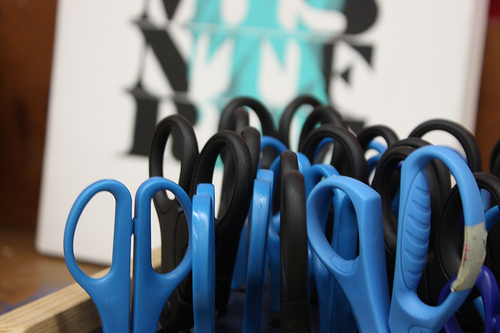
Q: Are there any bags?
A: No, there are no bags.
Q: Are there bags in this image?
A: No, there are no bags.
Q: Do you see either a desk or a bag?
A: No, there are no bags or desks.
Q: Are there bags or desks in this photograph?
A: No, there are no bags or desks.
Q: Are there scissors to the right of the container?
A: Yes, there are scissors to the right of the container.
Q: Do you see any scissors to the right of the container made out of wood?
A: Yes, there are scissors to the right of the container.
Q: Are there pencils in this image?
A: No, there are no pencils.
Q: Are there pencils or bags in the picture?
A: No, there are no pencils or bags.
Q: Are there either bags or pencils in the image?
A: No, there are no pencils or bags.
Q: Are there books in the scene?
A: No, there are no books.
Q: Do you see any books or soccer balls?
A: No, there are no books or soccer balls.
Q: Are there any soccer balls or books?
A: No, there are no books or soccer balls.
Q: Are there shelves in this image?
A: No, there are no shelves.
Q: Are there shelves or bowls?
A: No, there are no shelves or bowls.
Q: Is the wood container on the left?
A: Yes, the container is on the left of the image.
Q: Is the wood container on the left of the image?
A: Yes, the container is on the left of the image.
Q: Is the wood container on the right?
A: No, the container is on the left of the image.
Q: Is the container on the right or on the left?
A: The container is on the left of the image.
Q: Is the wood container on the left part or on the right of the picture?
A: The container is on the left of the image.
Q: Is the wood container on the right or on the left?
A: The container is on the left of the image.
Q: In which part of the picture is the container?
A: The container is on the left of the image.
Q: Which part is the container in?
A: The container is on the left of the image.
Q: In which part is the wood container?
A: The container is on the left of the image.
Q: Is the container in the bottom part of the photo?
A: Yes, the container is in the bottom of the image.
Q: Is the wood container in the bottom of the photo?
A: Yes, the container is in the bottom of the image.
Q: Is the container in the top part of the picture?
A: No, the container is in the bottom of the image.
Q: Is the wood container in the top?
A: No, the container is in the bottom of the image.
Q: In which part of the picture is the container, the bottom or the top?
A: The container is in the bottom of the image.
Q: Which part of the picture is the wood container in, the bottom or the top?
A: The container is in the bottom of the image.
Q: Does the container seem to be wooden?
A: Yes, the container is wooden.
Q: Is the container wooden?
A: Yes, the container is wooden.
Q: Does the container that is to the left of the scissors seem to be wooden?
A: Yes, the container is wooden.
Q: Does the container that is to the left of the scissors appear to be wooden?
A: Yes, the container is wooden.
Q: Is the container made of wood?
A: Yes, the container is made of wood.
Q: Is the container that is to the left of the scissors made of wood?
A: Yes, the container is made of wood.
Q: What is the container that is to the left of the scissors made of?
A: The container is made of wood.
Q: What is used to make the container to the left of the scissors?
A: The container is made of wood.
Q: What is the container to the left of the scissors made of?
A: The container is made of wood.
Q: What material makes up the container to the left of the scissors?
A: The container is made of wood.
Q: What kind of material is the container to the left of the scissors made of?
A: The container is made of wood.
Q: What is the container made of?
A: The container is made of wood.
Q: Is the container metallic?
A: No, the container is wooden.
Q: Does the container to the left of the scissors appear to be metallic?
A: No, the container is wooden.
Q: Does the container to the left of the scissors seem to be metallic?
A: No, the container is wooden.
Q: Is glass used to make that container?
A: No, the container is made of wood.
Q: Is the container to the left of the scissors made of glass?
A: No, the container is made of wood.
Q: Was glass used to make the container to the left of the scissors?
A: No, the container is made of wood.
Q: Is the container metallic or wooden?
A: The container is wooden.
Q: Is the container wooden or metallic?
A: The container is wooden.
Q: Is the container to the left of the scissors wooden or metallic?
A: The container is wooden.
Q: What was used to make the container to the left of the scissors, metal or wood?
A: The container is made of wood.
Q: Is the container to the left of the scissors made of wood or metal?
A: The container is made of wood.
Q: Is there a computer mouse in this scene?
A: No, there are no computer mice.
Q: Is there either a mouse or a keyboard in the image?
A: No, there are no computer mice or keyboards.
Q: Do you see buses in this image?
A: No, there are no buses.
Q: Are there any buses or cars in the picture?
A: No, there are no buses or cars.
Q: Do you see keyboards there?
A: No, there are no keyboards.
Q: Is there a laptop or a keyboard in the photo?
A: No, there are no keyboards or laptops.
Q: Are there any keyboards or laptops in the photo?
A: No, there are no keyboards or laptops.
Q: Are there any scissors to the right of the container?
A: Yes, there are scissors to the right of the container.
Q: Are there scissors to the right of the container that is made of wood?
A: Yes, there are scissors to the right of the container.